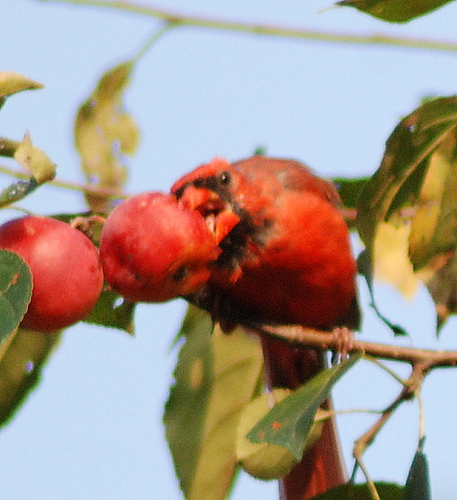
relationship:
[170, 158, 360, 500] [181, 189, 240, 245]
bird has beak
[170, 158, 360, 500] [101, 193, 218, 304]
bird eating fruit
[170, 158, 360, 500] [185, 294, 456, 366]
bird sitting on branch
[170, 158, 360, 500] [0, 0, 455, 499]
bird sitting in tree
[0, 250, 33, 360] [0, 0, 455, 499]
leaf hanging on tree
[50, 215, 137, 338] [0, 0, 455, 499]
leaf hanging on tree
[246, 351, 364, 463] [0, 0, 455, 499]
leaf hanging on tree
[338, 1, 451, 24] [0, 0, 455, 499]
leaf hanging on tree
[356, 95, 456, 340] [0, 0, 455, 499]
leaf hanging on tree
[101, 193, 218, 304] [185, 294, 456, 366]
fruit hanging from branch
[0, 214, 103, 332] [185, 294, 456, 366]
fruit hanging from branch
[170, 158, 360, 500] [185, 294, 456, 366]
bird grips branch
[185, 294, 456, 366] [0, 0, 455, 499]
branch of tree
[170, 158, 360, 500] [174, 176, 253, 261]
bird has marking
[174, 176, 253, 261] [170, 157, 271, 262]
marking on face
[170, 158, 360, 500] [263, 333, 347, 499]
bird has tail feathers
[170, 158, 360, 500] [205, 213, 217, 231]
bird has tongue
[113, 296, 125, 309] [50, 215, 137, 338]
hole in leaf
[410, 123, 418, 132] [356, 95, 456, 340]
hole in leaf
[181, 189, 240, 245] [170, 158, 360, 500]
beak of bird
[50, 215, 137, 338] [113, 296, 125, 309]
leaf has hole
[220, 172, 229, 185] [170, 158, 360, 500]
eye of bird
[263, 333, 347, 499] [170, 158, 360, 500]
tail feathers of bird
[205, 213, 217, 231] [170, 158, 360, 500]
tongue of bird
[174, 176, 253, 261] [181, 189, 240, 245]
marking around beak